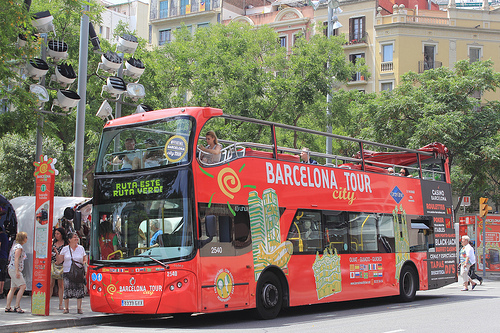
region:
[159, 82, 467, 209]
top deck is open on the bus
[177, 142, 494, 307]
double decker bus is red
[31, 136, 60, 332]
bus stop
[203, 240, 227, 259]
2540 is written on the bus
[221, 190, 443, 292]
pictures of buildings on the bus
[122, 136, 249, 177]
passengers on the top deck of bus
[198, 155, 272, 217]
picture of sun on the bus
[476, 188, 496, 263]
street light behind the bus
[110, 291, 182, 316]
license plate on front of bus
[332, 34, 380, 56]
flower box on window sill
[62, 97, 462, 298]
a double decker bus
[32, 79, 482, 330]
the bus is on the street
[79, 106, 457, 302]
the bus is red and black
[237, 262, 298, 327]
the wheel is black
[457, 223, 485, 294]
woman walking behind the bus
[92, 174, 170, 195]
green letters on the bus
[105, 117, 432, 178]
passengers on the top of the bus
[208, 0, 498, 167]
buildings to the left behind the bus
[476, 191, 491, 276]
a yellow traffic light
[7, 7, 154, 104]
a cluster of lights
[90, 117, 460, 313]
a double decker tour bus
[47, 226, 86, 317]
women standing on the sidewalk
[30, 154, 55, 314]
a tall red sign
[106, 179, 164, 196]
lcd screen on the front of a bus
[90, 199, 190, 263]
windshield on a bus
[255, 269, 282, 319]
front wheel of a bus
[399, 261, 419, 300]
rear wheel on a bus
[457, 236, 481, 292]
women walking across the street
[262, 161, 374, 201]
words on the side of a bus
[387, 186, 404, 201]
blue logo on a bus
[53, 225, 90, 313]
two woman near a curb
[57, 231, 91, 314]
woman with a bag slung across her chest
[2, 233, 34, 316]
woman on a sidewalk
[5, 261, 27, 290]
tan pants on a woman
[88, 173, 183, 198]
digital green text on the front of a bus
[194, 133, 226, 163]
a woman sitting on the upper level of a bus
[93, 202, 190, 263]
bus windshield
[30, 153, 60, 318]
red bus top sign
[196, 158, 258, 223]
sun graphic design on a bus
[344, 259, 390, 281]
flag designs on a red bus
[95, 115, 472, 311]
The bus has two levels.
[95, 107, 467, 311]
The bus is red.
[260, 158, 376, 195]
The lettering is white.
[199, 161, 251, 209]
The sun is yellow and green.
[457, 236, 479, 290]
The person is walking.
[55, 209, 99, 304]
People are getting on the bus.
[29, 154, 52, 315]
The sign is red.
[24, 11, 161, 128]
Many lights are on the poles.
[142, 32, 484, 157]
The trees are leafy.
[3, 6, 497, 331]
The sun is shining.